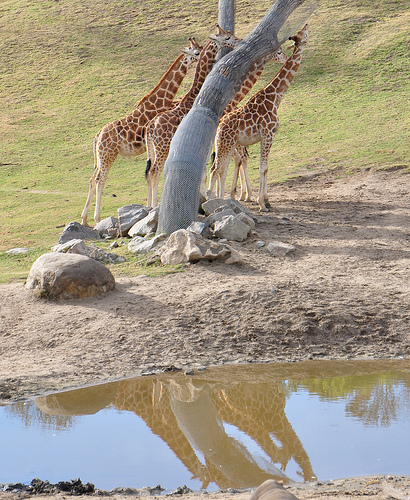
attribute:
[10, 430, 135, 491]
water — blue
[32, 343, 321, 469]
shadows — brown, long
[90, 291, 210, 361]
surface — grey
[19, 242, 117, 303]
rock — big, hard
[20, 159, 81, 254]
grass — green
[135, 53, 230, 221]
trunk — long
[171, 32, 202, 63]
eye — black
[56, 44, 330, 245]
giraffes — baby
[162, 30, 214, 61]
ears — short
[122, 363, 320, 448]
water — murky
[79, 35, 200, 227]
giraffe — facing right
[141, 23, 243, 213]
giraffe — facing right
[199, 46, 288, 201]
giraffe — facing right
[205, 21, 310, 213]
giraffe — facing right, looking up